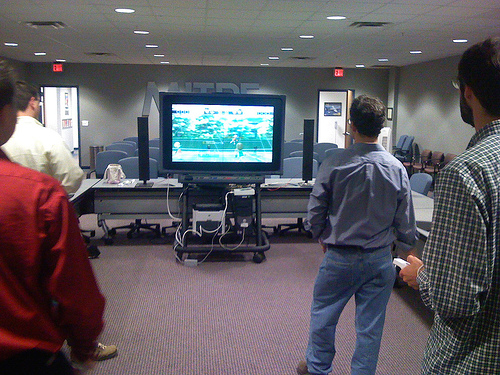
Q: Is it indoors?
A: Yes, it is indoors.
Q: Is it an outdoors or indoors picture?
A: It is indoors.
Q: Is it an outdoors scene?
A: No, it is indoors.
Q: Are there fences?
A: No, there are no fences.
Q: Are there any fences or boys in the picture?
A: No, there are no fences or boys.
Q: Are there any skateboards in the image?
A: No, there are no skateboards.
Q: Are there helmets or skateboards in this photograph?
A: No, there are no skateboards or helmets.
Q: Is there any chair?
A: Yes, there is a chair.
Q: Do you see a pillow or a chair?
A: Yes, there is a chair.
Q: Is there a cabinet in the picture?
A: No, there are no cabinets.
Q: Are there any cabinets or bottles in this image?
A: No, there are no cabinets or bottles.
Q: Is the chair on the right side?
A: Yes, the chair is on the right of the image.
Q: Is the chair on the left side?
A: No, the chair is on the right of the image.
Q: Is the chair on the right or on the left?
A: The chair is on the right of the image.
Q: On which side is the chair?
A: The chair is on the right of the image.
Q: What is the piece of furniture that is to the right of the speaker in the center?
A: The piece of furniture is a chair.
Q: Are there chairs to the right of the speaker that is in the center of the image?
A: Yes, there is a chair to the right of the speaker.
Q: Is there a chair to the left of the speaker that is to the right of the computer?
A: No, the chair is to the right of the speaker.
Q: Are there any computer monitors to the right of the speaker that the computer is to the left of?
A: No, there is a chair to the right of the speaker.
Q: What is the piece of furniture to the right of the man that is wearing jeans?
A: The piece of furniture is a chair.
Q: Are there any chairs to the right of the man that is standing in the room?
A: Yes, there is a chair to the right of the man.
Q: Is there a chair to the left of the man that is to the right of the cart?
A: No, the chair is to the right of the man.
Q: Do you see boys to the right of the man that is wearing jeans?
A: No, there is a chair to the right of the man.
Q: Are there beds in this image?
A: No, there are no beds.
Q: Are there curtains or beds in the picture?
A: No, there are no beds or curtains.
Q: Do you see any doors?
A: Yes, there is a door.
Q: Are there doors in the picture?
A: Yes, there is a door.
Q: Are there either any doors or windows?
A: Yes, there is a door.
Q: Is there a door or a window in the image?
A: Yes, there is a door.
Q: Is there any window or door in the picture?
A: Yes, there is a door.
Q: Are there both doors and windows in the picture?
A: No, there is a door but no windows.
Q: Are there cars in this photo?
A: No, there are no cars.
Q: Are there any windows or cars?
A: No, there are no cars or windows.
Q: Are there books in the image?
A: No, there are no books.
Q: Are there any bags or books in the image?
A: No, there are no books or bags.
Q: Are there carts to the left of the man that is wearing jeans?
A: Yes, there is a cart to the left of the man.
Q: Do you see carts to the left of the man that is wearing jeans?
A: Yes, there is a cart to the left of the man.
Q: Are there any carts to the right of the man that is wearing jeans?
A: No, the cart is to the left of the man.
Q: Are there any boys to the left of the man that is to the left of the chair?
A: No, there is a cart to the left of the man.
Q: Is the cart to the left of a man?
A: Yes, the cart is to the left of a man.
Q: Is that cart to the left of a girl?
A: No, the cart is to the left of a man.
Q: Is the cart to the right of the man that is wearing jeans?
A: No, the cart is to the left of the man.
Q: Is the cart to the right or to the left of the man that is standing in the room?
A: The cart is to the left of the man.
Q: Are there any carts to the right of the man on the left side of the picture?
A: Yes, there is a cart to the right of the man.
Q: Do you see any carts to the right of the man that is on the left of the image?
A: Yes, there is a cart to the right of the man.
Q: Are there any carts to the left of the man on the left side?
A: No, the cart is to the right of the man.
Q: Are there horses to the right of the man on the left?
A: No, there is a cart to the right of the man.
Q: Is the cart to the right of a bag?
A: No, the cart is to the right of the man.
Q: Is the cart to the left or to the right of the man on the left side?
A: The cart is to the right of the man.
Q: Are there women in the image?
A: No, there are no women.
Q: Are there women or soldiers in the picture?
A: No, there are no women or soldiers.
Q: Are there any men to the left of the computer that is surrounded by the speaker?
A: Yes, there is a man to the left of the computer.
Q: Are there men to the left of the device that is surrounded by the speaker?
A: Yes, there is a man to the left of the computer.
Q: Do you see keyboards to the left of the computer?
A: No, there is a man to the left of the computer.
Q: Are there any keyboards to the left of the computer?
A: No, there is a man to the left of the computer.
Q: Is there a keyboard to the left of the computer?
A: No, there is a man to the left of the computer.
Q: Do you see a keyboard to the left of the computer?
A: No, there is a man to the left of the computer.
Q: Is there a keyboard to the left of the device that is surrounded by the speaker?
A: No, there is a man to the left of the computer.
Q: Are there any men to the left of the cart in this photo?
A: Yes, there is a man to the left of the cart.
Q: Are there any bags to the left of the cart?
A: No, there is a man to the left of the cart.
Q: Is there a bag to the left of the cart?
A: No, there is a man to the left of the cart.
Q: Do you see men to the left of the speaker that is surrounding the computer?
A: Yes, there is a man to the left of the speaker.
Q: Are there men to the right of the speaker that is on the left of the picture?
A: No, the man is to the left of the speaker.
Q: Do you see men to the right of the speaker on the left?
A: No, the man is to the left of the speaker.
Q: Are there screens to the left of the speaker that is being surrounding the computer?
A: No, there is a man to the left of the speaker.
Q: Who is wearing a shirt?
A: The man is wearing a shirt.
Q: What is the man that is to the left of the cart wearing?
A: The man is wearing a shirt.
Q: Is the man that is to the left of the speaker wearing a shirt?
A: Yes, the man is wearing a shirt.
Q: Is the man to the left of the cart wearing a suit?
A: No, the man is wearing a shirt.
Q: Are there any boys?
A: No, there are no boys.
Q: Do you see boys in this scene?
A: No, there are no boys.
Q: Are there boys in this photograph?
A: No, there are no boys.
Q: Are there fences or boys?
A: No, there are no boys or fences.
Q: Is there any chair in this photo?
A: Yes, there is a chair.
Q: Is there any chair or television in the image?
A: Yes, there is a chair.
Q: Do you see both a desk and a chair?
A: Yes, there are both a chair and a desk.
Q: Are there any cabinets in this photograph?
A: No, there are no cabinets.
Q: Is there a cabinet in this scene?
A: No, there are no cabinets.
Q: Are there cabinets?
A: No, there are no cabinets.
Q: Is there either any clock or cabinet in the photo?
A: No, there are no cabinets or clocks.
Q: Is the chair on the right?
A: Yes, the chair is on the right of the image.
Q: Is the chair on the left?
A: No, the chair is on the right of the image.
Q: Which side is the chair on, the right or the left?
A: The chair is on the right of the image.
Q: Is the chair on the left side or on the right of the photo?
A: The chair is on the right of the image.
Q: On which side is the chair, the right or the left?
A: The chair is on the right of the image.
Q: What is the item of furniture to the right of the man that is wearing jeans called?
A: The piece of furniture is a chair.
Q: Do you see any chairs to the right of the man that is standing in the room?
A: Yes, there is a chair to the right of the man.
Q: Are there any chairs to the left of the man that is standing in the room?
A: No, the chair is to the right of the man.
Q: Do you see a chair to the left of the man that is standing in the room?
A: No, the chair is to the right of the man.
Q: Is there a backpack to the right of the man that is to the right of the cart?
A: No, there is a chair to the right of the man.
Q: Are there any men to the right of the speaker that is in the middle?
A: Yes, there is a man to the right of the speaker.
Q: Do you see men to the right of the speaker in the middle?
A: Yes, there is a man to the right of the speaker.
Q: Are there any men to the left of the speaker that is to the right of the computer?
A: No, the man is to the right of the speaker.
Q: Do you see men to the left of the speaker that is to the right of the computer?
A: No, the man is to the right of the speaker.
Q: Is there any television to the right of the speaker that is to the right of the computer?
A: No, there is a man to the right of the speaker.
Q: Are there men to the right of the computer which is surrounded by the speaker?
A: Yes, there is a man to the right of the computer.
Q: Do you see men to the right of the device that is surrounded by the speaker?
A: Yes, there is a man to the right of the computer.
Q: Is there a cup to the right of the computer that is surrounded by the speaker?
A: No, there is a man to the right of the computer.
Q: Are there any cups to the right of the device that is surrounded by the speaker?
A: No, there is a man to the right of the computer.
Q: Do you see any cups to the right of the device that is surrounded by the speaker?
A: No, there is a man to the right of the computer.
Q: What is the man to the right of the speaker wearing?
A: The man is wearing a shirt.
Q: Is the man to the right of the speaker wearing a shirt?
A: Yes, the man is wearing a shirt.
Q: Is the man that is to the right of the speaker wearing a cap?
A: No, the man is wearing a shirt.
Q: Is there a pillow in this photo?
A: No, there are no pillows.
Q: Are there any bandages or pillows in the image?
A: No, there are no pillows or bandages.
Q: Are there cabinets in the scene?
A: No, there are no cabinets.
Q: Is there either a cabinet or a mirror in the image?
A: No, there are no cabinets or mirrors.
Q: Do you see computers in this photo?
A: Yes, there is a computer.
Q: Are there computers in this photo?
A: Yes, there is a computer.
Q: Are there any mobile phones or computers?
A: Yes, there is a computer.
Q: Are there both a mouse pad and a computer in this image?
A: No, there is a computer but no mouse pads.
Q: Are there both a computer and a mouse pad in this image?
A: No, there is a computer but no mouse pads.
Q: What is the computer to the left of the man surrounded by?
A: The computer is surrounded by the speaker.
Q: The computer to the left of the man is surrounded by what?
A: The computer is surrounded by the speaker.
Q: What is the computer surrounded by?
A: The computer is surrounded by the speaker.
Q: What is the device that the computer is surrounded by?
A: The device is a speaker.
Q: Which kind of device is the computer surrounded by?
A: The computer is surrounded by the speaker.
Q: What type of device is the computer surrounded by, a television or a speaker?
A: The computer is surrounded by a speaker.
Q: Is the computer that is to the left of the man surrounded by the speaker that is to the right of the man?
A: Yes, the computer is surrounded by the speaker.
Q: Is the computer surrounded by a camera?
A: No, the computer is surrounded by the speaker.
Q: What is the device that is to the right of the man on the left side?
A: The device is a computer.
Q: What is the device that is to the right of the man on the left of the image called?
A: The device is a computer.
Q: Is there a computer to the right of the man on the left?
A: Yes, there is a computer to the right of the man.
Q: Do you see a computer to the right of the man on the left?
A: Yes, there is a computer to the right of the man.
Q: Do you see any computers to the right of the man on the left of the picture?
A: Yes, there is a computer to the right of the man.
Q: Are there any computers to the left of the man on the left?
A: No, the computer is to the right of the man.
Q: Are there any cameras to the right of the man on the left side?
A: No, there is a computer to the right of the man.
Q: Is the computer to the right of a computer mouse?
A: No, the computer is to the right of a man.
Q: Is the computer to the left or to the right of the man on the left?
A: The computer is to the right of the man.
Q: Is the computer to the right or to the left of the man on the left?
A: The computer is to the right of the man.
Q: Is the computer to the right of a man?
A: No, the computer is to the left of a man.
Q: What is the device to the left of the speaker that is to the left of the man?
A: The device is a computer.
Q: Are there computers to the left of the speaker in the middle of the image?
A: Yes, there is a computer to the left of the speaker.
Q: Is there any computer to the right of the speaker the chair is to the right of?
A: No, the computer is to the left of the speaker.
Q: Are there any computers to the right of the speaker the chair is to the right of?
A: No, the computer is to the left of the speaker.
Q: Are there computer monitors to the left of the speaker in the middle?
A: No, there is a computer to the left of the speaker.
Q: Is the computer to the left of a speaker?
A: Yes, the computer is to the left of a speaker.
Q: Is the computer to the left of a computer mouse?
A: No, the computer is to the left of a speaker.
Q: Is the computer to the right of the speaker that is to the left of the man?
A: No, the computer is to the left of the speaker.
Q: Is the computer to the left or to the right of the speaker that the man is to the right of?
A: The computer is to the left of the speaker.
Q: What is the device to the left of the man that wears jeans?
A: The device is a computer.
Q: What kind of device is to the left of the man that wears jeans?
A: The device is a computer.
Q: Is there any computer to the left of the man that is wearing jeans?
A: Yes, there is a computer to the left of the man.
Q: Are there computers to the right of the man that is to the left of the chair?
A: No, the computer is to the left of the man.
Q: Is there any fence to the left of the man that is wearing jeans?
A: No, there is a computer to the left of the man.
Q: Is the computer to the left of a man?
A: Yes, the computer is to the left of a man.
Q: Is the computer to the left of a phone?
A: No, the computer is to the left of a man.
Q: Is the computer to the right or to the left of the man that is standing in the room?
A: The computer is to the left of the man.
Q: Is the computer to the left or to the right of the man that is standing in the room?
A: The computer is to the left of the man.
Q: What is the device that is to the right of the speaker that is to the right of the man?
A: The device is a computer.